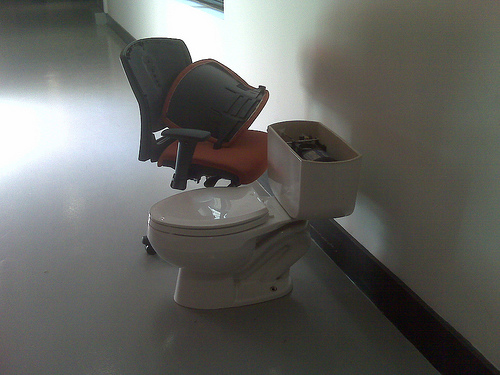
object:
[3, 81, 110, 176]
reflection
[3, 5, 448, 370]
floor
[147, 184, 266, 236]
lid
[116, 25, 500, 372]
trim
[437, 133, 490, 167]
ground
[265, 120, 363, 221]
holder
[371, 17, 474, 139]
bird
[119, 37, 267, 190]
chair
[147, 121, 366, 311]
toilet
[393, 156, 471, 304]
shape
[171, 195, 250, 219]
white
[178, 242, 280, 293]
white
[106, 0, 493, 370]
wall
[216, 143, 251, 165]
red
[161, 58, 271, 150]
broken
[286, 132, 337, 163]
parts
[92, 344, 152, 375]
part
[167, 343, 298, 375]
part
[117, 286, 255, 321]
part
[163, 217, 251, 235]
edge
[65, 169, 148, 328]
wall